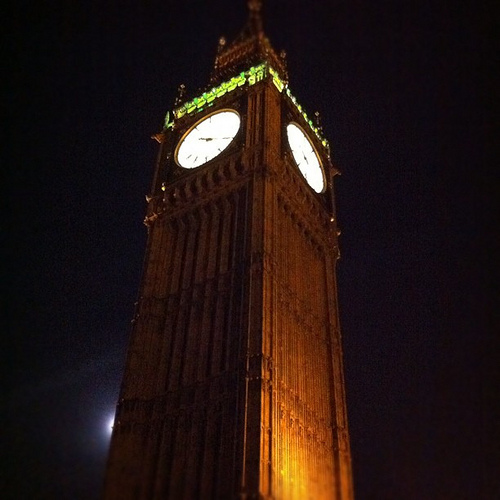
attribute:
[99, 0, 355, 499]
tower — brown, gold, here, bright, tall, yellow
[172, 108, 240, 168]
clock — white, here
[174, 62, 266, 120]
lights — shining, green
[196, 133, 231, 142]
hands — black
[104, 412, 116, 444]
moon — here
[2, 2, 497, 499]
sky — black, here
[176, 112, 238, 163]
numbers — black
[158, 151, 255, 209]
carvings — here